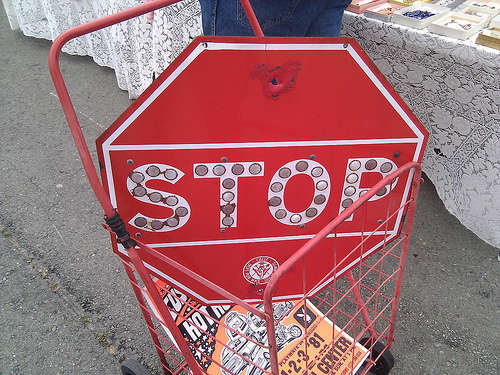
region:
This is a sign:
[132, 17, 392, 327]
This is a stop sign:
[65, 116, 209, 267]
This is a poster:
[139, 254, 282, 361]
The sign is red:
[178, 50, 332, 267]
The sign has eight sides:
[71, 68, 367, 365]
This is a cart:
[81, 157, 271, 315]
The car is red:
[155, 217, 239, 348]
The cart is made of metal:
[158, 306, 230, 368]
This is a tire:
[331, 336, 404, 370]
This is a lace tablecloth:
[439, 141, 493, 218]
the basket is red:
[44, 57, 369, 374]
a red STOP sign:
[91, 28, 391, 304]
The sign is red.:
[94, 63, 411, 305]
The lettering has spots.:
[118, 160, 396, 242]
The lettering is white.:
[118, 160, 396, 241]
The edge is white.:
[99, 43, 395, 308]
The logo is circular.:
[232, 252, 282, 289]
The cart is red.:
[38, 3, 434, 373]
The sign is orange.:
[142, 263, 342, 374]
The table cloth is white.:
[340, 20, 495, 215]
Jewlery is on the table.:
[354, 2, 499, 53]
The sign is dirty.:
[250, 57, 299, 99]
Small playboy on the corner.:
[294, 308, 318, 330]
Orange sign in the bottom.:
[154, 262, 319, 349]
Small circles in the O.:
[277, 162, 311, 190]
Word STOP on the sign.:
[111, 138, 409, 243]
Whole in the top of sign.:
[250, 49, 318, 111]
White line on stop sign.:
[114, 32, 404, 322]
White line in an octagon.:
[34, 3, 424, 348]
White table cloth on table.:
[385, 39, 423, 91]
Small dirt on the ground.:
[48, 91, 73, 242]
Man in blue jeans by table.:
[197, 2, 361, 52]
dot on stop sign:
[164, 168, 176, 178]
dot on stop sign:
[145, 160, 159, 179]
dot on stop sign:
[190, 160, 212, 182]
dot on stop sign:
[231, 159, 242, 174]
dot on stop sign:
[254, 163, 266, 173]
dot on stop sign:
[292, 156, 309, 178]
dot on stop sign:
[314, 195, 326, 207]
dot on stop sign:
[288, 208, 303, 231]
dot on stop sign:
[341, 171, 358, 183]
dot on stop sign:
[365, 150, 377, 168]